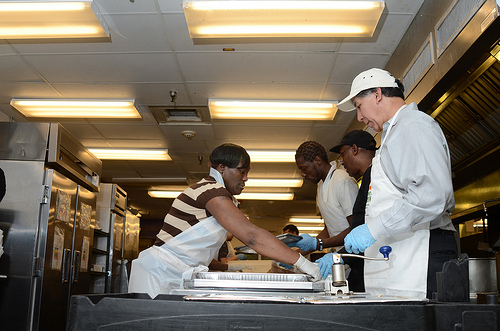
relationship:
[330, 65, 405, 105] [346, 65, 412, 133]
cap on head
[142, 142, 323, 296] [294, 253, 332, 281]
people wearing gloves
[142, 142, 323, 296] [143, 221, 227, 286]
people has apron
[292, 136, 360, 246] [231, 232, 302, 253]
worker holding tray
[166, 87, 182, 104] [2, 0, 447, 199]
sprinkler on ceiling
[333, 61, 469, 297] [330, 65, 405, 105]
man wearing cap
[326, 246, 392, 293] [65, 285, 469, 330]
can opener attached to table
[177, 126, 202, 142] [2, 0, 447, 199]
fire alarm attached to ceiling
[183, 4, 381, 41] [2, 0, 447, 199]
bulbs attached to ceiling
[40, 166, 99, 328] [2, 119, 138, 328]
doors on fridges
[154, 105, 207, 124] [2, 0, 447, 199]
air vents in ceiling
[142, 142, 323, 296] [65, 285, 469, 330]
people leaning over table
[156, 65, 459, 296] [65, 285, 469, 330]
people over table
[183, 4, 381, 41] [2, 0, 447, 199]
bulbs on ceiling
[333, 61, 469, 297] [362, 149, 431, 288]
man wearing apron